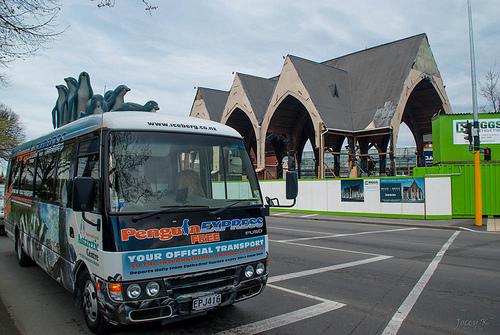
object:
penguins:
[73, 71, 91, 118]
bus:
[4, 108, 270, 329]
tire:
[77, 270, 110, 334]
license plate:
[191, 295, 225, 312]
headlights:
[126, 282, 144, 298]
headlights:
[242, 264, 255, 278]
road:
[3, 217, 497, 333]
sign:
[337, 174, 365, 202]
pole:
[466, 1, 482, 229]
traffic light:
[460, 120, 474, 150]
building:
[188, 32, 450, 179]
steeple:
[414, 27, 434, 55]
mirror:
[283, 168, 299, 200]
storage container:
[430, 111, 498, 165]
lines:
[374, 226, 462, 334]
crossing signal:
[484, 146, 491, 162]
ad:
[120, 216, 264, 246]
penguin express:
[118, 215, 265, 240]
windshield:
[106, 132, 247, 208]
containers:
[431, 114, 499, 164]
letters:
[118, 227, 138, 242]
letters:
[128, 254, 137, 262]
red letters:
[129, 261, 140, 270]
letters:
[200, 220, 215, 232]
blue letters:
[199, 221, 211, 233]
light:
[107, 282, 123, 295]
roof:
[191, 29, 452, 137]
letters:
[77, 234, 98, 251]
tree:
[0, 0, 67, 82]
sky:
[1, 0, 496, 113]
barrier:
[210, 174, 455, 218]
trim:
[214, 172, 468, 185]